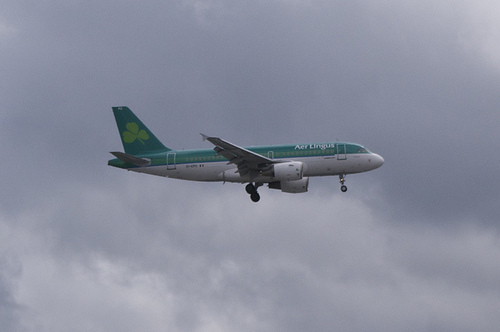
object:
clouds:
[0, 200, 165, 329]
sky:
[0, 16, 500, 108]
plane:
[104, 105, 385, 204]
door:
[335, 143, 347, 161]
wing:
[197, 131, 278, 176]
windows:
[274, 144, 336, 158]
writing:
[293, 143, 337, 150]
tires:
[340, 185, 349, 193]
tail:
[106, 102, 166, 152]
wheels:
[245, 183, 257, 195]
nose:
[367, 150, 386, 170]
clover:
[121, 122, 150, 147]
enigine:
[269, 157, 306, 182]